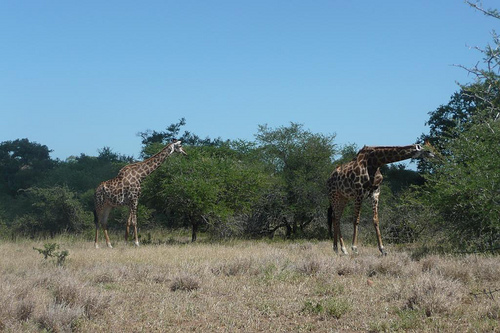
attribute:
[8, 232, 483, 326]
grass — yellow, dry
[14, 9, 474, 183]
sky — blue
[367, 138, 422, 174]
neck — giraffe's, horizontal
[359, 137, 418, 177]
neck — giraffe's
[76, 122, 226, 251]
giraffe — brown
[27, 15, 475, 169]
sky — blue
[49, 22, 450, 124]
clouds — white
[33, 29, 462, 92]
clouds — white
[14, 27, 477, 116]
sky — blue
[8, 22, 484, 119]
sky — blue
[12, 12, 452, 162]
clouds — white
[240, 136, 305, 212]
leaves — green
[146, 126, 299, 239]
leaves — green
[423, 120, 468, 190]
leaves — green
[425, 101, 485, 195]
leaves — green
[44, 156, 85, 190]
leaves — green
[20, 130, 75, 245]
leaves — green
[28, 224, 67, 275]
bush — small leafy green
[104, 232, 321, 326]
grass — brown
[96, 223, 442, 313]
grass — tall tufted brown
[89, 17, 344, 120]
sky — clear cloudless blue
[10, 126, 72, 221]
tree — tall dark green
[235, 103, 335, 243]
trees — small scrubby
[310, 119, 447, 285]
giraffe — Left foreleg 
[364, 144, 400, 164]
neck — giraffe's long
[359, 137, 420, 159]
neck — giraffe's long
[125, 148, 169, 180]
neck — giraffe's long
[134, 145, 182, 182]
neck — giraffe's long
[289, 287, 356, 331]
grass — dried , patch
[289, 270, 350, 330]
grass — patch, dried 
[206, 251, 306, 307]
grass — dried , patch 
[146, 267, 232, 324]
grass — patch , dried 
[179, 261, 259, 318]
grass — dried , patch 